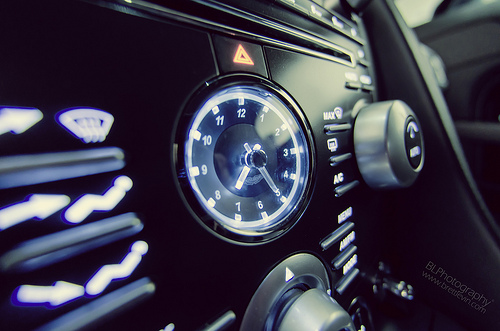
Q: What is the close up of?
A: Car controls.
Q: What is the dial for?
A: Time.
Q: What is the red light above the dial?
A: Parking lights.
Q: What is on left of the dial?
A: Ac controls.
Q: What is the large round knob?
A: Volume control.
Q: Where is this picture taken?
A: In a car.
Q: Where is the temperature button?
A: To the left at the top.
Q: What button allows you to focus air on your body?
A: The button in the middle to the left.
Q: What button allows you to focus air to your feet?
A: The button button to the left with the arrow pointing to the feet.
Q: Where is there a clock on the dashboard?
A: In the middle to the right of the air controls.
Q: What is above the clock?
A: Emergency blinker button.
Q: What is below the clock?
A: A knob.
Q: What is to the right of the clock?
A: A knob.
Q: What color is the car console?
A: Black.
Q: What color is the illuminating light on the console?
A: White.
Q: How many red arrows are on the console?
A: One.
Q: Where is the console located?
A: Vehicle.